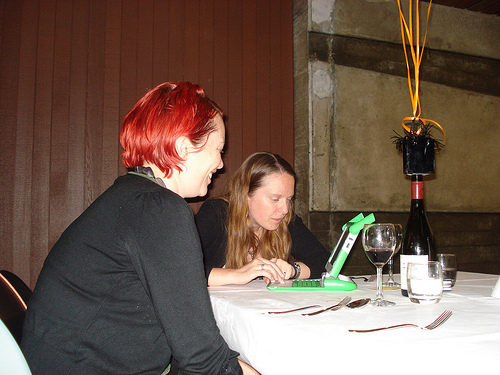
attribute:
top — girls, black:
[194, 194, 329, 284]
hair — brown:
[236, 147, 301, 182]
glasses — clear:
[359, 223, 408, 304]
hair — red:
[116, 76, 221, 178]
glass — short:
[402, 257, 446, 307]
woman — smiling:
[19, 78, 235, 373]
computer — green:
[267, 205, 377, 295]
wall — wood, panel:
[1, 0, 294, 291]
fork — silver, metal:
[358, 296, 468, 347]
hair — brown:
[224, 150, 294, 268]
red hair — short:
[122, 81, 224, 179]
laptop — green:
[262, 206, 377, 293]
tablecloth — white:
[206, 269, 484, 371]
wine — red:
[365, 247, 395, 267]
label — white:
[397, 250, 431, 290]